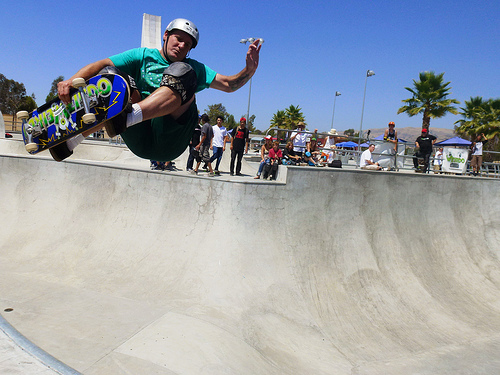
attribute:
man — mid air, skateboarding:
[47, 16, 263, 163]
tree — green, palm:
[397, 68, 460, 159]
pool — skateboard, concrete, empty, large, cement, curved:
[3, 153, 497, 374]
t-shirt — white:
[210, 122, 228, 148]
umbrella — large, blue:
[436, 136, 475, 147]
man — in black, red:
[228, 115, 250, 176]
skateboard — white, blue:
[12, 71, 131, 154]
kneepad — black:
[163, 59, 198, 102]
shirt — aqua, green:
[108, 44, 212, 110]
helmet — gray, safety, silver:
[163, 18, 200, 48]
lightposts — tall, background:
[358, 67, 378, 136]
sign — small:
[440, 145, 470, 178]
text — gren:
[445, 153, 466, 164]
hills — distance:
[353, 121, 500, 165]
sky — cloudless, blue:
[2, 0, 500, 134]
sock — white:
[124, 102, 143, 132]